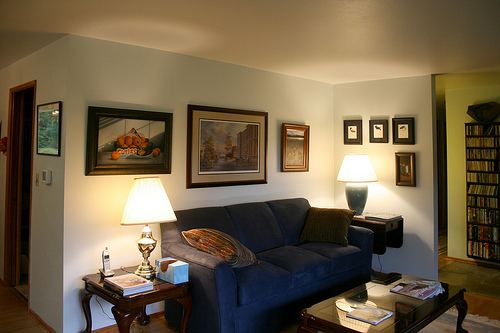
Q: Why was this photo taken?
A: To show the living room.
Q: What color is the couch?
A: Blue.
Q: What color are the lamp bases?
A: Silver.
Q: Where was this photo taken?
A: In someone's living room.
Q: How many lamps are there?
A: 2.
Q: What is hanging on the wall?
A: Pictures.